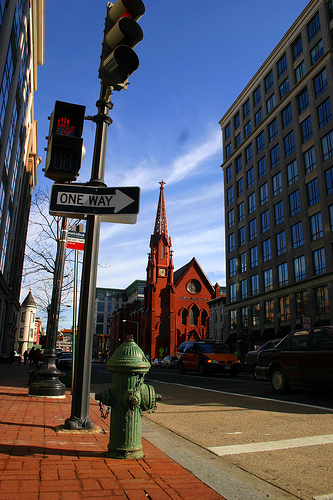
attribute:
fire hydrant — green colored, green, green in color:
[95, 333, 163, 460]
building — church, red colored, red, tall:
[107, 181, 228, 363]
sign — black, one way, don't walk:
[50, 184, 143, 223]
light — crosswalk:
[39, 99, 88, 183]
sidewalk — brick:
[0, 351, 218, 499]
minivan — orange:
[172, 336, 243, 378]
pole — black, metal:
[41, 4, 146, 436]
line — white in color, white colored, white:
[211, 431, 332, 458]